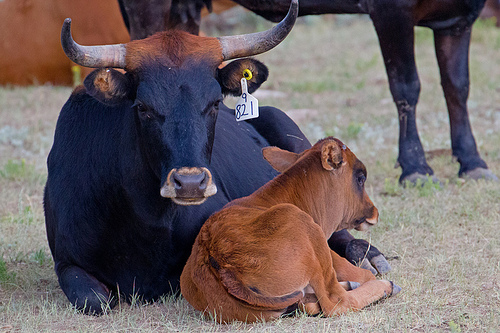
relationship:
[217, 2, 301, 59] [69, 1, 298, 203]
horn sticking out of head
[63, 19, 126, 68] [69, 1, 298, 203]
horn sticking out of head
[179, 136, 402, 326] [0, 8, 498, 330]
baby cow laying on ground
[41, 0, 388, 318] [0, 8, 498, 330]
adult cow laying on ground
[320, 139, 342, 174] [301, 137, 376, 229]
ear on side of head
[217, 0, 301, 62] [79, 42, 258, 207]
horn coming out of head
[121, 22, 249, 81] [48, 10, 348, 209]
fur on top of head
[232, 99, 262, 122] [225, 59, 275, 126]
numbers on tag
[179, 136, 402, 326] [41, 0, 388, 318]
baby cow laying next to adult cow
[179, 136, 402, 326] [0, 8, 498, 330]
baby cow laying down on ground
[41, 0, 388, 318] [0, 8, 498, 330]
adult cow laying down on ground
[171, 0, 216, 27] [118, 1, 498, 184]
utters on cow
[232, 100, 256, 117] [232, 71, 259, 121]
numbers written on tag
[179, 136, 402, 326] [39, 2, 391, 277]
baby cow laying by cow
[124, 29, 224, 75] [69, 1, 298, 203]
top of head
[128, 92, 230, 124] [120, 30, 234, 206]
eyes on either side of head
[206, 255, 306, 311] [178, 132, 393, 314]
tail curled under body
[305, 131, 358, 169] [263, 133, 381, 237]
ear on side of head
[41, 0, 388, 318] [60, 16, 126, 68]
adult cow on horn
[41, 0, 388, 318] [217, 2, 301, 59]
adult cow on horn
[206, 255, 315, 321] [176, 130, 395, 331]
tail on body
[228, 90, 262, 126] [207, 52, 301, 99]
tag on ear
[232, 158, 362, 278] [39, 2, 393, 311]
baby cow laying by adult cow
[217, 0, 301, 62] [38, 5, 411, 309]
horn are on bull